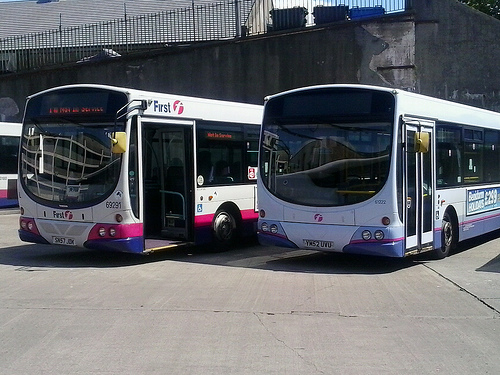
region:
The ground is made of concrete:
[68, 286, 403, 356]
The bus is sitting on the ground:
[11, 76, 253, 269]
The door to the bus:
[130, 110, 202, 255]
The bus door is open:
[135, 112, 203, 262]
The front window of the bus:
[253, 110, 398, 220]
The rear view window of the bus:
[396, 113, 433, 158]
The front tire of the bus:
[431, 208, 458, 261]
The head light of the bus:
[358, 221, 388, 248]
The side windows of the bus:
[436, 125, 498, 191]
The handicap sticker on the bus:
[193, 197, 206, 215]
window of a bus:
[319, 153, 329, 165]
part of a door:
[408, 170, 413, 192]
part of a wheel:
[442, 223, 448, 241]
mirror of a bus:
[418, 133, 425, 148]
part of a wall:
[262, 67, 271, 79]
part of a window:
[231, 158, 240, 170]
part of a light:
[108, 225, 120, 238]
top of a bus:
[114, 82, 119, 92]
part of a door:
[179, 169, 199, 209]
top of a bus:
[283, 88, 287, 100]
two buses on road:
[41, 62, 472, 317]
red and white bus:
[1, 84, 263, 294]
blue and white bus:
[285, 67, 497, 277]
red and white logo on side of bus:
[137, 89, 183, 119]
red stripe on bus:
[91, 198, 246, 242]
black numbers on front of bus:
[99, 195, 131, 219]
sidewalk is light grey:
[143, 297, 277, 364]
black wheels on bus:
[211, 200, 263, 251]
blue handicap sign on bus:
[192, 192, 204, 223]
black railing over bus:
[47, 0, 310, 70]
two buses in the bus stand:
[26, 85, 493, 287]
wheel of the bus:
[207, 194, 252, 256]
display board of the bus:
[22, 93, 121, 120]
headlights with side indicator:
[10, 217, 135, 247]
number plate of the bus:
[49, 236, 76, 243]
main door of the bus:
[135, 117, 205, 247]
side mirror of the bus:
[414, 130, 436, 151]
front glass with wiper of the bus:
[263, 100, 385, 200]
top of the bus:
[45, 76, 274, 112]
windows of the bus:
[207, 124, 248, 182]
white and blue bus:
[257, 82, 499, 259]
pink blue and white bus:
[16, 83, 263, 261]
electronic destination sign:
[41, 99, 106, 117]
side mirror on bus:
[411, 133, 429, 152]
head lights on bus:
[20, 220, 32, 231]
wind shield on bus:
[261, 123, 392, 204]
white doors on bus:
[404, 125, 436, 247]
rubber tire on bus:
[209, 205, 240, 250]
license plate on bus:
[303, 239, 330, 251]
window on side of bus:
[438, 122, 498, 187]